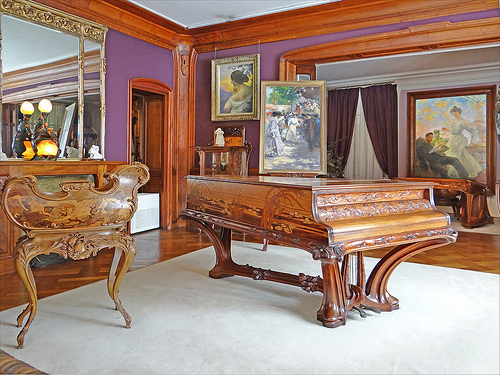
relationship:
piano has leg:
[179, 173, 459, 329] [316, 260, 349, 329]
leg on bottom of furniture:
[112, 228, 136, 329] [0, 161, 150, 350]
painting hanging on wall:
[208, 53, 261, 123] [192, 8, 500, 177]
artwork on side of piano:
[186, 178, 328, 246] [179, 173, 459, 329]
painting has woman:
[208, 53, 261, 123] [223, 70, 253, 114]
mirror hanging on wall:
[0, 12, 104, 158] [104, 26, 176, 229]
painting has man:
[414, 93, 488, 187] [415, 132, 469, 180]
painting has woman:
[414, 93, 488, 187] [441, 105, 483, 180]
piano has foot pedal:
[179, 173, 459, 329] [353, 304, 369, 319]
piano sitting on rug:
[179, 173, 459, 329] [1, 239, 500, 375]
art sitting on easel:
[257, 81, 328, 175] [268, 171, 318, 178]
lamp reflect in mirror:
[30, 97, 62, 159] [0, 12, 104, 158]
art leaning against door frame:
[257, 81, 328, 175] [278, 16, 499, 80]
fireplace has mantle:
[20, 174, 99, 270] [0, 159, 129, 177]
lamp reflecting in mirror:
[30, 97, 62, 159] [0, 12, 104, 158]